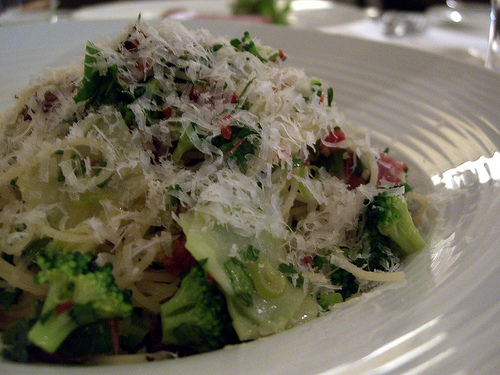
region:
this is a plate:
[391, 309, 458, 373]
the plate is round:
[369, 295, 491, 370]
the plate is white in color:
[347, 301, 422, 333]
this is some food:
[21, 40, 393, 355]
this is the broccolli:
[8, 250, 218, 340]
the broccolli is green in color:
[31, 270, 155, 322]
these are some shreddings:
[51, 155, 164, 189]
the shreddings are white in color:
[51, 115, 112, 167]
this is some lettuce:
[202, 230, 251, 242]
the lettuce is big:
[211, 228, 231, 252]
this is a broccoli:
[33, 268, 103, 338]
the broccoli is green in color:
[38, 263, 102, 354]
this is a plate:
[412, 270, 494, 361]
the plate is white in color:
[423, 273, 485, 373]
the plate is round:
[375, 50, 450, 123]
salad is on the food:
[198, 175, 263, 222]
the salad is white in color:
[259, 93, 315, 141]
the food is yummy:
[239, 275, 295, 327]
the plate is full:
[17, 38, 316, 308]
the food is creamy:
[255, 286, 297, 334]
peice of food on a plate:
[11, 240, 130, 361]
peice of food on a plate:
[155, 259, 224, 354]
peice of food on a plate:
[364, 187, 432, 260]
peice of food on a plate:
[327, 249, 411, 291]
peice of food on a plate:
[175, 198, 313, 329]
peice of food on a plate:
[4, 129, 121, 204]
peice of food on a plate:
[227, 28, 265, 67]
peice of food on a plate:
[67, 40, 120, 111]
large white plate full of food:
[0, 24, 499, 373]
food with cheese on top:
[0, 10, 443, 373]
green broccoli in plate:
[33, 268, 111, 351]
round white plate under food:
[13, 8, 498, 344]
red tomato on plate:
[366, 142, 409, 190]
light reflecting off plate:
[409, 138, 481, 191]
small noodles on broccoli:
[43, 86, 143, 206]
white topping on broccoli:
[165, 135, 301, 248]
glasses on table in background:
[346, 5, 487, 56]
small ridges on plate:
[348, 46, 491, 170]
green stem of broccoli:
[28, 280, 124, 373]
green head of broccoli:
[48, 247, 153, 317]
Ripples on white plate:
[380, 305, 427, 355]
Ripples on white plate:
[326, 337, 375, 374]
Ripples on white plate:
[414, 325, 458, 370]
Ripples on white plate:
[407, 100, 453, 150]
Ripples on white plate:
[438, 135, 495, 217]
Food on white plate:
[33, 30, 376, 346]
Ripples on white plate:
[22, 27, 44, 60]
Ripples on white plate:
[352, 297, 415, 360]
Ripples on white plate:
[415, 252, 472, 311]